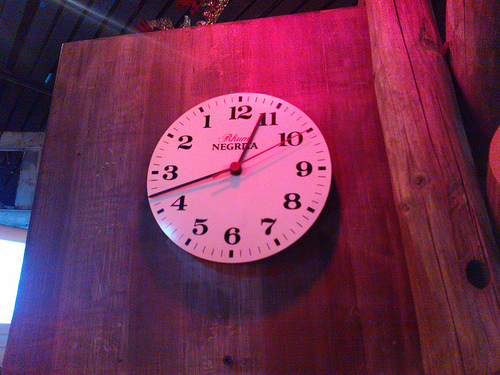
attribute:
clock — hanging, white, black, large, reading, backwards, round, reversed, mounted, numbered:
[145, 90, 335, 265]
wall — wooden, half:
[8, 4, 425, 370]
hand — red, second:
[213, 132, 300, 184]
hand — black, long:
[151, 162, 245, 196]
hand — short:
[230, 112, 265, 173]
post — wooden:
[363, 1, 498, 374]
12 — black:
[231, 103, 252, 119]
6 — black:
[224, 223, 241, 243]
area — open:
[3, 238, 25, 325]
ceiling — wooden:
[2, 2, 362, 128]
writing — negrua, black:
[212, 141, 258, 149]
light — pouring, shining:
[2, 239, 28, 329]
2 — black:
[178, 131, 193, 152]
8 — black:
[282, 191, 301, 211]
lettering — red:
[218, 131, 249, 140]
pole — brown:
[444, 0, 500, 195]